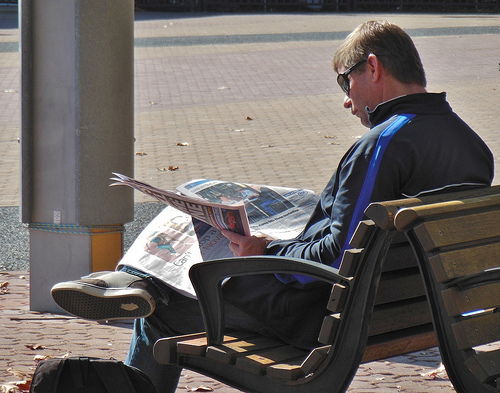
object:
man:
[49, 19, 500, 392]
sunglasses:
[337, 59, 366, 95]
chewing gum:
[120, 304, 139, 311]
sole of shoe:
[50, 269, 159, 322]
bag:
[31, 356, 154, 392]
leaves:
[24, 339, 48, 349]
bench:
[149, 182, 500, 392]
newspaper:
[109, 169, 320, 300]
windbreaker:
[263, 91, 494, 291]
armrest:
[188, 256, 346, 348]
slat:
[414, 211, 499, 254]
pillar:
[19, 1, 134, 314]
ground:
[1, 0, 500, 393]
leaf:
[189, 387, 213, 392]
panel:
[90, 229, 123, 277]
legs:
[123, 294, 303, 392]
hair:
[334, 20, 433, 90]